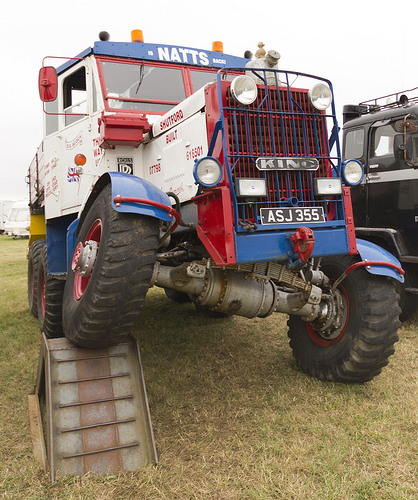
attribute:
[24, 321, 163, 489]
ramp — metal 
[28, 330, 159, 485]
jack — silver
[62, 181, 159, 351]
tire — black, big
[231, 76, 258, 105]
headlight — round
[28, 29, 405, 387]
truck — white, blue, large, black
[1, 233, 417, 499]
grass — dry, brown, green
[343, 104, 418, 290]
car — black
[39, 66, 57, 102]
side mirror — red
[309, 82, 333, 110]
headlight — round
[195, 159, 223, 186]
headlight — round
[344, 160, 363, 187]
headlight — round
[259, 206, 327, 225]
license plate — black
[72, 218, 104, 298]
wheel — red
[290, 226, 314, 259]
clamp — red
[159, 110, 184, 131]
sticker — red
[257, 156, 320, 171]
sign — black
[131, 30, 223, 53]
lights — orange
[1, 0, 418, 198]
sky — white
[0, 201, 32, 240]
trailers — white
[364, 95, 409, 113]
horn — silver